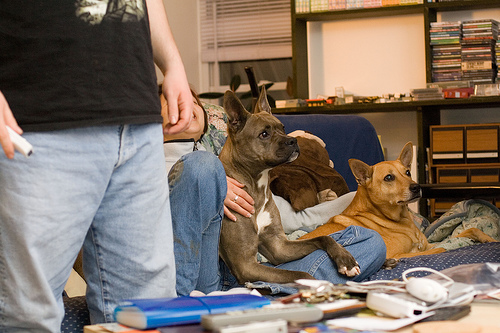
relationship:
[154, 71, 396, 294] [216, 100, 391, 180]
person sitting couch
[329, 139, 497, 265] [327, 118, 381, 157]
dog sitting couch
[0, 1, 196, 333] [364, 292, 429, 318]
man playing wii remote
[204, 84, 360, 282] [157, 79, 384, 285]
dog with person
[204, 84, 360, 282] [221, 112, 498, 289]
dog on couch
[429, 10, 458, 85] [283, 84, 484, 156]
stack on desk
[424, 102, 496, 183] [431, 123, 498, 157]
desk has cd holder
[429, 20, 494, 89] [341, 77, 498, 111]
cd cases on shelf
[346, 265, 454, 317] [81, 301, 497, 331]
wii remote on table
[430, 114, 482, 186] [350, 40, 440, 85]
wooden boxes on wall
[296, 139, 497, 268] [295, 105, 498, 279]
dog on couch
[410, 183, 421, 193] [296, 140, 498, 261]
nose on dog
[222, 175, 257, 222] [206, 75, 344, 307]
hand on dog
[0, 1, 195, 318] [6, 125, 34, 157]
man holds controller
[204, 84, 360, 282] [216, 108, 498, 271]
dog sitting on couch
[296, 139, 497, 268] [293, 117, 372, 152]
dog sitting on couch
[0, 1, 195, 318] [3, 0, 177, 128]
man wearing a t-shirt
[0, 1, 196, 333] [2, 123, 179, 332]
man wearing a blue jeans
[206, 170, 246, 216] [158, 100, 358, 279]
hand on a dog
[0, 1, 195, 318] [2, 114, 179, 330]
man wearing blue jeans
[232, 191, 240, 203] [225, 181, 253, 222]
ring on hand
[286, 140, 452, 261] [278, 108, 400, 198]
dog laying on couch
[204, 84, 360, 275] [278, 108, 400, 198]
dog laying on couch